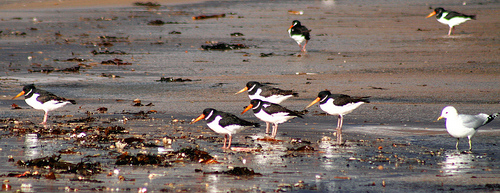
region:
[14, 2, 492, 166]
group of eight birds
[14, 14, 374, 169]
six black and white birds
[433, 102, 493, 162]
one white and gray bird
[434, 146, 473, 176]
reflection of the white bird on the ground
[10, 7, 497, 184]
birds standing on a beach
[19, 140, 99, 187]
debris on the ground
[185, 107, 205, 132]
skinny orange beak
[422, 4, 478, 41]
side profile of a bird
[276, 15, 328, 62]
front angle view of a bird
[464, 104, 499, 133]
feathers on the tail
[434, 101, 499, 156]
Seagull on right has yellow beak and white head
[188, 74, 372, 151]
Group of seabirds have orange beaks and black and white bodies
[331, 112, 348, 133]
Seabird has short pink legs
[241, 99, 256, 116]
Sea bird in center has bright orange beak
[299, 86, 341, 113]
Sea bird has a white stripe on throat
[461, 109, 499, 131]
Seagull has a gray back and black tail feathers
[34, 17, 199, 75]
Debris scattered across beach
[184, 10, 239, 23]
Piece of driftwood is in background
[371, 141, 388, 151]
There is a small orange object on ground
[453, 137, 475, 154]
Seagull's legs are pale yellow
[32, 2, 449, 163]
birds are on beach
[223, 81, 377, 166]
black and white birds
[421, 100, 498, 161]
white birds with black tail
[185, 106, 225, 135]
bird has orange beak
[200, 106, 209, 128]
white streak on head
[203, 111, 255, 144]
bird has white breast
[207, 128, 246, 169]
bird has orange legs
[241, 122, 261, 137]
bird has black tail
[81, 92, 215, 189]
brown detritus on beach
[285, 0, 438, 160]
sand on beach is dark brown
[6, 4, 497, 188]
several seabirds on the shore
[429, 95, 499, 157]
a gray and white seagull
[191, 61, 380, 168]
four white and black skimmer birds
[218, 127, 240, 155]
the two feet on a seabird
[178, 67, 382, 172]
several seabirds in a group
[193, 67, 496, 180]
one seagull and four other seabirds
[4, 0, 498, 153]
eight seabirds on the beach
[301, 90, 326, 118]
the orange bill of a seabird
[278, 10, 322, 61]
a seabird walking away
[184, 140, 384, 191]
the reflection of seabirds on the sand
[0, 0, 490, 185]
Birds on the beach.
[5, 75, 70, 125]
A bird on the beach.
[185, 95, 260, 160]
The second bird on the beach.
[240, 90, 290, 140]
The third bird on the beach.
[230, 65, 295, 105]
The fourth bird on the beach.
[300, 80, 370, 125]
The fifth bird on the beach.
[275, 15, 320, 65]
The sixth bird on the beach.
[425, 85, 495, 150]
The seventh bird on the beach.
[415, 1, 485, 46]
The eighth bird on the beach.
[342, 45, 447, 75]
Sand on the beach.